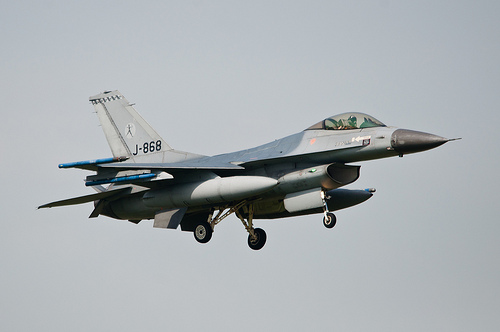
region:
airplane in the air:
[47, 57, 441, 294]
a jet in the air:
[42, 29, 418, 276]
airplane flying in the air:
[48, 39, 499, 270]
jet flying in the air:
[41, 52, 472, 315]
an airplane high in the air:
[22, 52, 496, 313]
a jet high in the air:
[25, 30, 482, 330]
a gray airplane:
[32, 35, 481, 214]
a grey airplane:
[47, 57, 466, 267]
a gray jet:
[14, 60, 491, 285]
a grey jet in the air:
[42, 60, 495, 313]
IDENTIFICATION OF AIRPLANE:
[130, 138, 171, 161]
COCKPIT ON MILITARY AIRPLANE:
[310, 110, 390, 133]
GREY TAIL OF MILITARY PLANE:
[66, 87, 191, 157]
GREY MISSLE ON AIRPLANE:
[121, 173, 283, 210]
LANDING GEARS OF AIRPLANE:
[186, 216, 275, 251]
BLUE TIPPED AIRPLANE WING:
[55, 154, 245, 179]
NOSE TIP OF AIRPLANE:
[387, 122, 474, 162]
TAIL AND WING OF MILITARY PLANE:
[36, 85, 247, 210]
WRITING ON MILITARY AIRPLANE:
[341, 135, 386, 150]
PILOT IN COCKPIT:
[337, 112, 362, 132]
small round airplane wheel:
[247, 220, 267, 253]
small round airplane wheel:
[241, 225, 271, 246]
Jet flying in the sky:
[26, 65, 494, 228]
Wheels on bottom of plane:
[171, 211, 431, 261]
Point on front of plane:
[417, 98, 469, 172]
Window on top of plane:
[310, 94, 401, 155]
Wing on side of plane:
[70, 135, 290, 223]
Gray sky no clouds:
[147, 19, 284, 146]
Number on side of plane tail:
[122, 127, 179, 169]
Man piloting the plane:
[334, 109, 364, 133]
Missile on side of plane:
[136, 173, 284, 204]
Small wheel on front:
[315, 215, 343, 233]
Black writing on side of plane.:
[126, 137, 195, 163]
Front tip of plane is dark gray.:
[377, 120, 480, 165]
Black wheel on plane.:
[313, 203, 348, 247]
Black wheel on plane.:
[242, 230, 291, 265]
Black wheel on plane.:
[186, 206, 239, 293]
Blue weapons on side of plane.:
[53, 144, 163, 194]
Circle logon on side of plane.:
[123, 115, 148, 140]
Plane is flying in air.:
[92, 101, 394, 248]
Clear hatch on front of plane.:
[328, 91, 405, 160]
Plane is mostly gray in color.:
[98, 126, 413, 201]